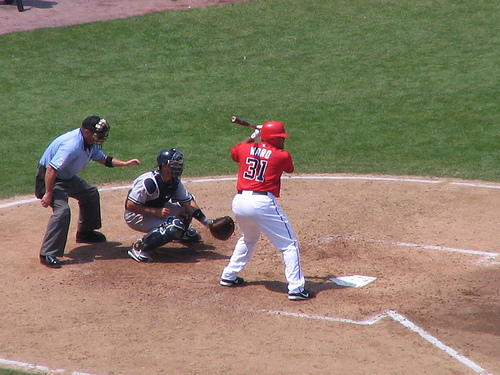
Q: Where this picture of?
A: A baseball field.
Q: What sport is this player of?
A: Baseball.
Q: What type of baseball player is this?
A: A batter.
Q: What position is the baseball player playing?
A: A catcher.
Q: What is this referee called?
A: An umpire.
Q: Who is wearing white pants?
A: The batter.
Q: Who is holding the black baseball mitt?
A: The catcher.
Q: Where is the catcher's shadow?
A: On the dirt.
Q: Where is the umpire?
A: Behind the catcher.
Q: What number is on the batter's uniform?
A: 31.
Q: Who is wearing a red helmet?
A: The batter.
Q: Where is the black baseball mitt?
A: In catcher's left hand.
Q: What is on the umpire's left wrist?
A: Black wristband.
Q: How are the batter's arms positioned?
A: Left arm behind right arm.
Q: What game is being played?
A: Baseball.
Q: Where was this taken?
A: Baseball field.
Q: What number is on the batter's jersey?
A: 31.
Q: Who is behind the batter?
A: The catcher.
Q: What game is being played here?
A: Baseball.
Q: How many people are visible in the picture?
A: Three.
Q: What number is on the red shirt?
A: 31.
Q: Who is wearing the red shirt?
A: The batter.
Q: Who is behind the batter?
A: The catcher.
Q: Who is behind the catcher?
A: The umpire.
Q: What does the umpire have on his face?
A: A wire mask.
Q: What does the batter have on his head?
A: A helmet.